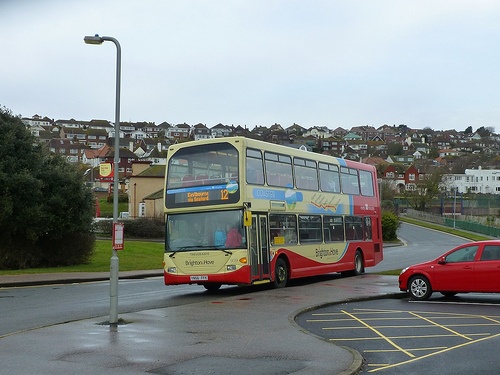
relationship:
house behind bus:
[386, 162, 418, 183] [159, 129, 393, 294]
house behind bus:
[126, 129, 151, 159] [159, 129, 393, 294]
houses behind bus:
[104, 146, 138, 176] [153, 120, 391, 309]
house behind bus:
[157, 124, 195, 144] [159, 129, 393, 294]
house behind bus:
[306, 124, 326, 144] [159, 129, 393, 294]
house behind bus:
[301, 122, 339, 140] [159, 129, 393, 294]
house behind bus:
[24, 109, 58, 132] [159, 129, 393, 294]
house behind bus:
[66, 124, 86, 138] [159, 129, 393, 294]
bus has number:
[159, 129, 393, 294] [184, 190, 209, 202]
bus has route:
[159, 129, 393, 294] [215, 183, 229, 199]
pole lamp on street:
[81, 28, 139, 337] [12, 263, 159, 353]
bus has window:
[159, 129, 393, 294] [159, 209, 249, 254]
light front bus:
[221, 260, 242, 276] [159, 129, 393, 294]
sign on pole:
[112, 222, 125, 251] [81, 25, 131, 341]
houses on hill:
[24, 113, 499, 196] [25, 114, 498, 196]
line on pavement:
[340, 309, 417, 358] [298, 290, 499, 373]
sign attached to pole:
[111, 218, 124, 251] [84, 34, 122, 325]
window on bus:
[168, 143, 239, 189] [159, 135, 384, 294]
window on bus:
[168, 208, 247, 252] [159, 135, 384, 294]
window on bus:
[243, 145, 265, 186] [159, 135, 384, 294]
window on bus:
[261, 147, 296, 191] [159, 135, 384, 294]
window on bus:
[294, 154, 321, 192] [159, 135, 384, 294]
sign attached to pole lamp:
[112, 222, 125, 251] [82, 33, 123, 322]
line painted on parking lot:
[340, 309, 417, 358] [297, 290, 499, 373]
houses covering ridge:
[24, 113, 499, 196] [23, 116, 499, 204]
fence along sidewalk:
[400, 187, 499, 240] [399, 213, 499, 237]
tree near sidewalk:
[1, 105, 98, 268] [0, 269, 162, 286]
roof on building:
[130, 156, 163, 178] [127, 156, 164, 218]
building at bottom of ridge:
[439, 166, 499, 196] [23, 116, 499, 204]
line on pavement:
[340, 306, 411, 356] [298, 290, 499, 373]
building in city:
[386, 169, 426, 192] [47, 121, 487, 207]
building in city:
[439, 166, 499, 196] [29, 120, 496, 201]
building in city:
[340, 130, 360, 141] [22, 117, 496, 217]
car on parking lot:
[396, 238, 500, 302] [292, 292, 499, 374]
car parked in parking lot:
[398, 238, 498, 299] [297, 290, 499, 373]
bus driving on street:
[159, 135, 384, 294] [1, 220, 477, 373]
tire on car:
[407, 272, 431, 300] [398, 238, 498, 299]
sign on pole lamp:
[112, 222, 125, 251] [82, 33, 123, 322]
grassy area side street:
[121, 238, 159, 268] [13, 274, 294, 352]